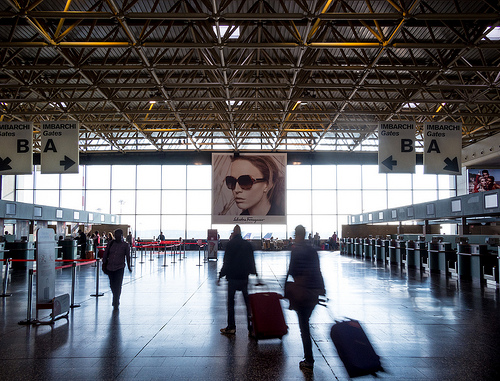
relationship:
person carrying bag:
[283, 224, 329, 372] [324, 301, 381, 379]